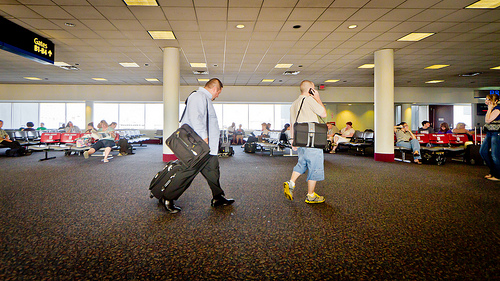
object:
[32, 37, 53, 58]
sign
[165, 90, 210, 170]
bags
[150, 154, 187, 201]
bags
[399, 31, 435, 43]
lights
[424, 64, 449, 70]
lights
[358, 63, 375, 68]
lights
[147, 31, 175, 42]
lights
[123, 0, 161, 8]
lights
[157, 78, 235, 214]
man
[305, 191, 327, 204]
shoes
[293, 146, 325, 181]
shorts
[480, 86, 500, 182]
woman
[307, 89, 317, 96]
cell phone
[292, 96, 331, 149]
bag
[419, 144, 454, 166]
bicycle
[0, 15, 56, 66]
board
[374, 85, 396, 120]
ground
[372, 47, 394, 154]
pole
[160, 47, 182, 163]
pole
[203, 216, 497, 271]
carpeting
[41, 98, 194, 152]
sun shinine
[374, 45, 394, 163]
beam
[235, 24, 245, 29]
light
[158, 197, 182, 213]
shoe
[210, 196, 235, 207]
shoe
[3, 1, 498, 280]
airport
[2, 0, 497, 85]
ceiling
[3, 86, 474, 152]
windows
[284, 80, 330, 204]
man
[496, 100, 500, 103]
phone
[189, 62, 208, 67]
light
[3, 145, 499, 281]
floor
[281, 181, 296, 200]
shoes